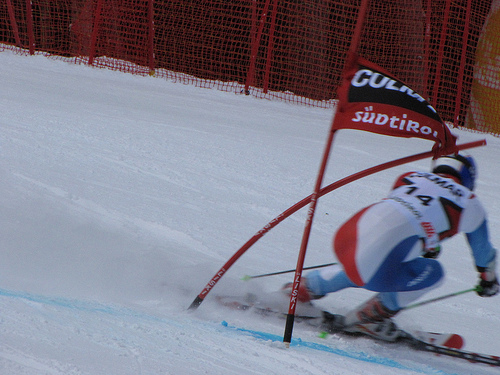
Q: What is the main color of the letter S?
A: White.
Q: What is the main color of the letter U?
A: White.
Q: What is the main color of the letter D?
A: White.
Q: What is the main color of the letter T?
A: White.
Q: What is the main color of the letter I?
A: White.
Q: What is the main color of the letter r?
A: White.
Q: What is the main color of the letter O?
A: White.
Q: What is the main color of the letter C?
A: White.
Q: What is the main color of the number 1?
A: Black.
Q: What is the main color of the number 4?
A: Black.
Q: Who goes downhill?
A: The skier.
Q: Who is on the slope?
A: The skier.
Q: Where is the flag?
A: On the pole.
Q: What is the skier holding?
A: Poles.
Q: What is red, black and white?
A: The flag.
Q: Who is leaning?
A: The skier?.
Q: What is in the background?
A: A net.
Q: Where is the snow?
A: On the ground.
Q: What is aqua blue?
A: The course guide.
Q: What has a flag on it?
A: The pole.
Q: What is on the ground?
A: Snow.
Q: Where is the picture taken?
A: Ski slope.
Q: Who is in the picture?
A: Skier.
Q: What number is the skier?
A: 14.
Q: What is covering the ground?
A: Snow.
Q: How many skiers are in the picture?
A: One.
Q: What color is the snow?
A: White.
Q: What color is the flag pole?
A: Red.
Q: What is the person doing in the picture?
A: Skiing.